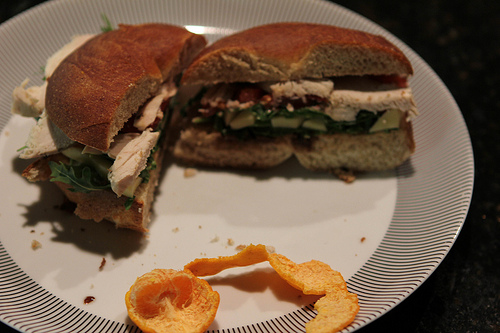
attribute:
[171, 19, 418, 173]
burger — cut, brown, big, half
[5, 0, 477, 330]
plate — white, big, black, striped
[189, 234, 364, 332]
peel — orange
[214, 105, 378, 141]
veggies — green, leafy, green colored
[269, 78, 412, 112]
chicken — white, mixed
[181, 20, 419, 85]
bread — brown, wheat, sliced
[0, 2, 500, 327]
counter — black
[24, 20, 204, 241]
burger — cut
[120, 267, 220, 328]
clementine — half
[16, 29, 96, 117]
chicken — discarded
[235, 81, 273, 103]
tomato — sliced